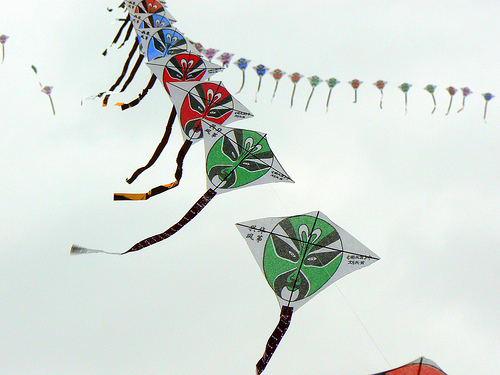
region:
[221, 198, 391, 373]
This is a kite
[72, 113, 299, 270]
This is a kite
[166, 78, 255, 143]
This is a kite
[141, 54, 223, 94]
This is a kite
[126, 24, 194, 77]
This is a kite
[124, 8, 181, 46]
This is a kite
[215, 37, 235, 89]
This is a kite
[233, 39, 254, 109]
This is a kite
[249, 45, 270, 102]
This is a kite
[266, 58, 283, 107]
This is a kite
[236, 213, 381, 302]
green and white kite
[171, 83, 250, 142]
red and white kite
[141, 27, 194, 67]
blue and white kite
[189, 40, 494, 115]
line of colored kites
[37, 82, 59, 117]
kites flying in sky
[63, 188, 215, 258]
black and white kite tail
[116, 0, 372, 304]
line of kites in the air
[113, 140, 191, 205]
yellow and black kite tail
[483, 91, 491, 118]
blue kite in air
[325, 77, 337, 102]
green kite in air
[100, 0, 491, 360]
A string of colorful kites.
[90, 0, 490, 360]
The kites are flying in the sky.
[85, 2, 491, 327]
All the kites have similar design.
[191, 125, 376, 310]
Kites with black, grey and green colored design.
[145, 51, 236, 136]
Kites with black, red and grey colored design.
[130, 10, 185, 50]
Kites with black, grey and blue colored design.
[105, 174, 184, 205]
Kite with yellow and black tail.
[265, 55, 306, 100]
Orange flying kites.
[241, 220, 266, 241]
Kite with some Chinese words written on it.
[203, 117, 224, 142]
The Chinese words are written in black.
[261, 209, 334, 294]
A green mask on the kite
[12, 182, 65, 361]
The sky above the kites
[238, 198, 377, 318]
The kite is shaped like a diamond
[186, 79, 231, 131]
A blue mask on the kite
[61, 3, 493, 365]
Kites flown in the air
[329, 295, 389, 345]
A string connecting two kites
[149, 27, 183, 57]
A blue mask on the kite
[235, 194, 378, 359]
A kite in the air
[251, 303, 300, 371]
A black strap below the kite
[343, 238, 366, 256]
The kite has a white background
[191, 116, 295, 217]
This is a kite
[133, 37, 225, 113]
This is a kite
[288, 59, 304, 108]
This is a kite